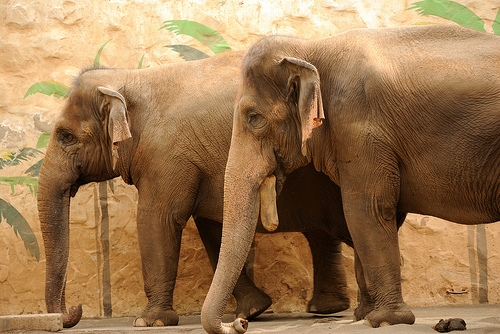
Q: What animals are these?
A: Elephants.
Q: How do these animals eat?
A: With their trunks.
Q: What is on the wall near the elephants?
A: Drawn leaves.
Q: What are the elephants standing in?
A: Sand.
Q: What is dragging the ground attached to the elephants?
A: Their trunks.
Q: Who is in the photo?
A: No people.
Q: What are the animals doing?
A: Walking.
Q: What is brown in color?
A: The elephants.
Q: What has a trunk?
A: Elephant.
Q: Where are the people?
A: None in photo.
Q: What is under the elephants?
A: Ground.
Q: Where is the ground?
A: Under animals.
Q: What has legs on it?
A: Elephant.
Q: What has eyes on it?
A: The elephant.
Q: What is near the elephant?
A: Wall.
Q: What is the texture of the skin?
A: Wrinkled.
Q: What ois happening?
A: Elephants standing.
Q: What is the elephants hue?
A: Brow.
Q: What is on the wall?
A: Trees.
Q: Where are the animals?
A: In front of the wall.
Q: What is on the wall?
A: Green leaves.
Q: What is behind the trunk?
A: Front legs.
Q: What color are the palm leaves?
A: Green.